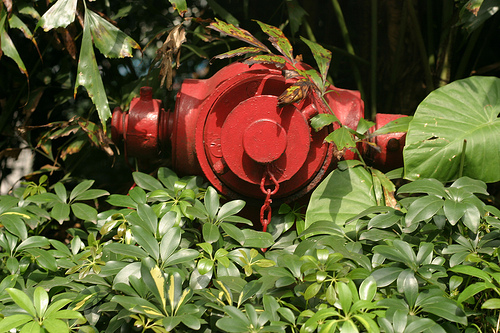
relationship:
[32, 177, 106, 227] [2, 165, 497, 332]
leaves on bush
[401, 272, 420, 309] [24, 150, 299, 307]
leaf on plant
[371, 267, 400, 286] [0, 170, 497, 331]
leaf on plant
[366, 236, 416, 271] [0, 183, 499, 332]
leaf on bush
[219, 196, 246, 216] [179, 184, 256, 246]
leaf on plant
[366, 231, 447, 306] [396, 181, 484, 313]
leaves on branch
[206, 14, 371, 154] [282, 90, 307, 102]
branch with spots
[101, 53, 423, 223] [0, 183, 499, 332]
fire hydrant in bush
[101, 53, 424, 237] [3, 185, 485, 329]
fire hydrant behind bush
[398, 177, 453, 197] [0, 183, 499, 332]
leaf on bush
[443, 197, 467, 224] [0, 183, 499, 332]
leaf on bush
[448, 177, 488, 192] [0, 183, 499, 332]
leaf on bush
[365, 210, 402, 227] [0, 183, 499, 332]
leaf on bush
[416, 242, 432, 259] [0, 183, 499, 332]
leaf on bush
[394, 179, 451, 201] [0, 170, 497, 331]
leaf on plant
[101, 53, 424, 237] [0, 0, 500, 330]
fire hydrant in a bush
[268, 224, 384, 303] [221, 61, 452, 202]
leaves on a branch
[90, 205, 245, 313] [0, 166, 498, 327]
leaves on a branch